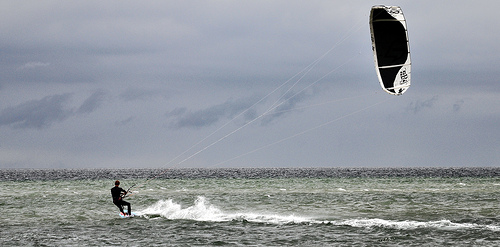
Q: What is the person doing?
A: Para-sailing.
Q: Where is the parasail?
A: In the air.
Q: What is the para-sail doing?
A: Flying.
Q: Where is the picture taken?
A: The ocean.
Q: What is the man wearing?
A: Wetsuit.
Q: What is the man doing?
A: Kiteboarding.